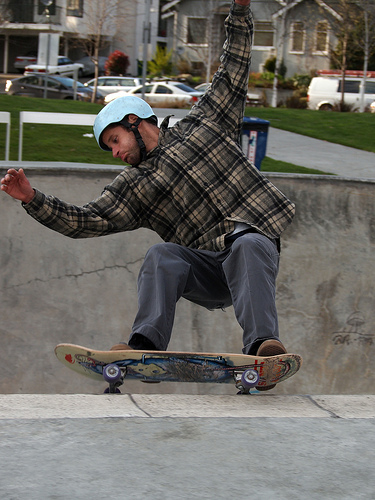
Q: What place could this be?
A: It is a park.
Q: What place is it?
A: It is a park.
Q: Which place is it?
A: It is a park.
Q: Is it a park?
A: Yes, it is a park.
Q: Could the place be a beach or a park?
A: It is a park.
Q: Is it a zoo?
A: No, it is a park.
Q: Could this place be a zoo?
A: No, it is a park.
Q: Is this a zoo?
A: No, it is a park.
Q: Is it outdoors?
A: Yes, it is outdoors.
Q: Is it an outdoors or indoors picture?
A: It is outdoors.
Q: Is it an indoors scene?
A: No, it is outdoors.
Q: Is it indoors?
A: No, it is outdoors.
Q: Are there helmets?
A: Yes, there is a helmet.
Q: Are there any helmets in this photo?
A: Yes, there is a helmet.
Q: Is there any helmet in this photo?
A: Yes, there is a helmet.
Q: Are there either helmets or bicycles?
A: Yes, there is a helmet.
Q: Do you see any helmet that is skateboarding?
A: Yes, there is a helmet that is skateboarding.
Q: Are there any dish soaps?
A: No, there are no dish soaps.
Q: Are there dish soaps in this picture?
A: No, there are no dish soaps.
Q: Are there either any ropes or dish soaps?
A: No, there are no dish soaps or ropes.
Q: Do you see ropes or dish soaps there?
A: No, there are no dish soaps or ropes.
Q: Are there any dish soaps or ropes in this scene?
A: No, there are no dish soaps or ropes.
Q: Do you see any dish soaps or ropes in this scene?
A: No, there are no dish soaps or ropes.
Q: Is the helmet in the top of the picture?
A: Yes, the helmet is in the top of the image.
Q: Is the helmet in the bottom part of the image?
A: No, the helmet is in the top of the image.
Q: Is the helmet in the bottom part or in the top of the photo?
A: The helmet is in the top of the image.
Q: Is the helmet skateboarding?
A: Yes, the helmet is skateboarding.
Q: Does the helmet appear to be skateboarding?
A: Yes, the helmet is skateboarding.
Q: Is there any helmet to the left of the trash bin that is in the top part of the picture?
A: Yes, there is a helmet to the left of the trash bin.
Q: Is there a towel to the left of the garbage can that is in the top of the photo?
A: No, there is a helmet to the left of the trashcan.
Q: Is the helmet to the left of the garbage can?
A: Yes, the helmet is to the left of the garbage can.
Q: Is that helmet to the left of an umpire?
A: No, the helmet is to the left of the garbage can.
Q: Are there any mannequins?
A: No, there are no mannequins.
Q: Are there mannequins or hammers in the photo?
A: No, there are no mannequins or hammers.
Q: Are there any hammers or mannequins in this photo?
A: No, there are no mannequins or hammers.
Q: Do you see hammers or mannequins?
A: No, there are no mannequins or hammers.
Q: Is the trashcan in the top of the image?
A: Yes, the trashcan is in the top of the image.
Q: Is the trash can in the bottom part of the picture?
A: No, the trash can is in the top of the image.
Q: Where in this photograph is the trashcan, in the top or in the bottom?
A: The trashcan is in the top of the image.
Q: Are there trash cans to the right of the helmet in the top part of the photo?
A: Yes, there is a trash can to the right of the helmet.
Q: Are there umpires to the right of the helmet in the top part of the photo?
A: No, there is a trash can to the right of the helmet.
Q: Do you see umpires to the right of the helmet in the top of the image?
A: No, there is a trash can to the right of the helmet.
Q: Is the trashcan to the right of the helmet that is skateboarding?
A: Yes, the trashcan is to the right of the helmet.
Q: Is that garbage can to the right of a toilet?
A: No, the garbage can is to the right of the helmet.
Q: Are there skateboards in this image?
A: Yes, there is a skateboard.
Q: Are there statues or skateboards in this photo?
A: Yes, there is a skateboard.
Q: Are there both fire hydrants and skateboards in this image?
A: No, there is a skateboard but no fire hydrants.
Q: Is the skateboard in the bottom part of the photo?
A: Yes, the skateboard is in the bottom of the image.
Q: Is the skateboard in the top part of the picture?
A: No, the skateboard is in the bottom of the image.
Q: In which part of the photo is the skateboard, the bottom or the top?
A: The skateboard is in the bottom of the image.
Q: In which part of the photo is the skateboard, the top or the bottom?
A: The skateboard is in the bottom of the image.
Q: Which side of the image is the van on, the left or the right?
A: The van is on the right of the image.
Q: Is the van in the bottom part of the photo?
A: No, the van is in the top of the image.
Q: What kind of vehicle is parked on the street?
A: The vehicle is a van.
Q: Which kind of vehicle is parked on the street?
A: The vehicle is a van.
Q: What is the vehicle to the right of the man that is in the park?
A: The vehicle is a van.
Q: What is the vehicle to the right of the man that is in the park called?
A: The vehicle is a van.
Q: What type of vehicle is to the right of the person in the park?
A: The vehicle is a van.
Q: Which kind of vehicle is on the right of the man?
A: The vehicle is a van.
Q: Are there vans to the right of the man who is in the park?
A: Yes, there is a van to the right of the man.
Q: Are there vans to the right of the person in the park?
A: Yes, there is a van to the right of the man.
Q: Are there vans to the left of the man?
A: No, the van is to the right of the man.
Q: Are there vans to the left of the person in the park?
A: No, the van is to the right of the man.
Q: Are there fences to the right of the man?
A: No, there is a van to the right of the man.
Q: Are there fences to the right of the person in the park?
A: No, there is a van to the right of the man.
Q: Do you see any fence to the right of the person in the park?
A: No, there is a van to the right of the man.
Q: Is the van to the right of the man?
A: Yes, the van is to the right of the man.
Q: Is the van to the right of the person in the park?
A: Yes, the van is to the right of the man.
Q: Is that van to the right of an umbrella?
A: No, the van is to the right of the man.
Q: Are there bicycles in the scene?
A: No, there are no bicycles.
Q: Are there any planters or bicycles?
A: No, there are no bicycles or planters.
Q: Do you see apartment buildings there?
A: No, there are no apartment buildings.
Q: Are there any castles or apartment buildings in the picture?
A: No, there are no apartment buildings or castles.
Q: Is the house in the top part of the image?
A: Yes, the house is in the top of the image.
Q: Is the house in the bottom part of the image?
A: No, the house is in the top of the image.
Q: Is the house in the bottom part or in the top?
A: The house is in the top of the image.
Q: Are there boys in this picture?
A: No, there are no boys.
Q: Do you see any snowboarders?
A: No, there are no snowboarders.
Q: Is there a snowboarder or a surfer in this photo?
A: No, there are no snowboarders or surfers.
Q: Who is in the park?
A: The man is in the park.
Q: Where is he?
A: The man is in the park.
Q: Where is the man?
A: The man is in the park.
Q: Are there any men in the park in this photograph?
A: Yes, there is a man in the park.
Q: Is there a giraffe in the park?
A: No, there is a man in the park.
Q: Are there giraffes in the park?
A: No, there is a man in the park.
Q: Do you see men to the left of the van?
A: Yes, there is a man to the left of the van.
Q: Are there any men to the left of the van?
A: Yes, there is a man to the left of the van.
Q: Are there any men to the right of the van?
A: No, the man is to the left of the van.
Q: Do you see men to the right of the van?
A: No, the man is to the left of the van.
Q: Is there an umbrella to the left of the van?
A: No, there is a man to the left of the van.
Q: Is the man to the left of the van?
A: Yes, the man is to the left of the van.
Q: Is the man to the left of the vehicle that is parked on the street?
A: Yes, the man is to the left of the van.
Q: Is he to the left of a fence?
A: No, the man is to the left of the van.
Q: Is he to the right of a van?
A: No, the man is to the left of a van.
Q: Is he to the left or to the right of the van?
A: The man is to the left of the van.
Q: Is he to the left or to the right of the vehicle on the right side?
A: The man is to the left of the van.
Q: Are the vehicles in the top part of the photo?
A: Yes, the vehicles are in the top of the image.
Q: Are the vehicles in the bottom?
A: No, the vehicles are in the top of the image.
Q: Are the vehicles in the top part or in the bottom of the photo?
A: The vehicles are in the top of the image.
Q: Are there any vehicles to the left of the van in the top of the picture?
A: Yes, there are vehicles to the left of the van.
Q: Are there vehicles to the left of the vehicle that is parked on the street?
A: Yes, there are vehicles to the left of the van.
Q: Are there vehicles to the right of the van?
A: No, the vehicles are to the left of the van.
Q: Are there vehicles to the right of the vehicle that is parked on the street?
A: No, the vehicles are to the left of the van.